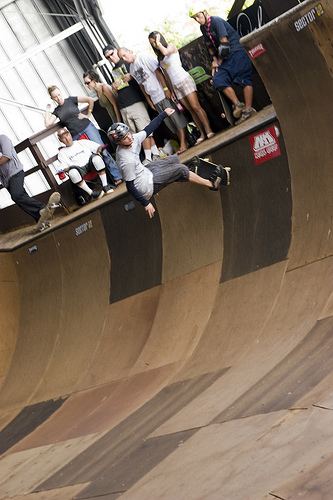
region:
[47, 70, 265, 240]
a skater doing tricks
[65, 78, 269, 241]
the ramp is plywood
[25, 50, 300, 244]
people are watching the skater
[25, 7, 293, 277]
the ramp is indoors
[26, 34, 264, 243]
the skater wears a helmet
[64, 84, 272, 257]
the helmet is black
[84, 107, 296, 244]
the skater's shirt is grey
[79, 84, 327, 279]
the skater wears shorts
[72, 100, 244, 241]
the shorts are grey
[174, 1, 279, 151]
this skater wears blue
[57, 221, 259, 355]
Wooden pipe for skateboards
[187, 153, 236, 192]
Skateboard being ridden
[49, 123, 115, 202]
Skateboarder waiting his turn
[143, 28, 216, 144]
Spectator of skateboarders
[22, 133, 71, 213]
Safety rail on skateboard pipe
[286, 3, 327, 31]
Sticker on skateboard pipe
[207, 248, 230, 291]
Seam in wood of skateboard pipe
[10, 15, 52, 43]
Metal siding of building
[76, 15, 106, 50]
Support post of building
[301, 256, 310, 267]
Fastener used to secure wood on skateboard pipe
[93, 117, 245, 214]
the man is skateboarding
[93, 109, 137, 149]
man is wearing a helmet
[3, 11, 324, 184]
people are watching man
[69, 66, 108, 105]
woman wearing sunglasses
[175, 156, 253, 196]
the skateboard is black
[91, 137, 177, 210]
man's shirt is gray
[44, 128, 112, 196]
man is sitting down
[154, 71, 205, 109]
girl is wearing shorts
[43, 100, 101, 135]
woman's shorts are black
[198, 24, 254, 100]
man is wearing blue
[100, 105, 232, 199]
Skateboard on halfpipe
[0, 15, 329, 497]
Large wooden halfpipe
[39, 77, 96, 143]
Girl with black shirt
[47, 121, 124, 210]
Man sitting in folding chair watching skateboarder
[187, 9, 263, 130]
Skateboarder watching sport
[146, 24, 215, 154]
Girl fixing her hair in the crowd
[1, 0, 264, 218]
Spectators watching skateboarder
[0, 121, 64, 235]
Skateboarder waiting his turn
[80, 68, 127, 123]
Woman with green shirt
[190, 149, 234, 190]
Black and wooden skateboard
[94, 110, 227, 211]
The man is skateboarding.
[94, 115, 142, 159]
He is wearing a helmet.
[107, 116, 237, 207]
He is wearing a grey shirt.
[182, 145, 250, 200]
The skateboard is black.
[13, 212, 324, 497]
The half pipe is brown.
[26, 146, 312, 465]
The half pipe is dark and light brown.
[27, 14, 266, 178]
The other skaters are waiting their turn.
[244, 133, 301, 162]
The sign is red and white.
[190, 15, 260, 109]
He is wearing blue.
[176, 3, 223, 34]
He is wearing a yellow helmet.